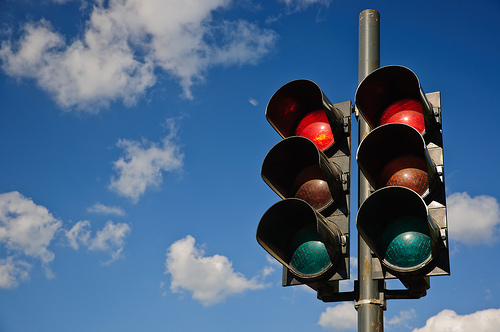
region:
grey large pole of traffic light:
[345, 3, 400, 325]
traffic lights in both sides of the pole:
[252, 66, 445, 296]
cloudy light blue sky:
[0, 8, 499, 325]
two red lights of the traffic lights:
[276, 78, 433, 140]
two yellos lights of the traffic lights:
[263, 136, 448, 200]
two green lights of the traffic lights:
[269, 209, 434, 274]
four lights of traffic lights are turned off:
[265, 130, 450, 285]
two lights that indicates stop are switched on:
[280, 68, 435, 158]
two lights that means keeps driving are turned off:
[271, 196, 447, 278]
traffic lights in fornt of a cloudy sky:
[258, 6, 447, 330]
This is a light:
[248, 16, 475, 310]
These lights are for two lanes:
[260, 70, 464, 308]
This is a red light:
[263, 55, 448, 142]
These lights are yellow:
[263, 125, 445, 199]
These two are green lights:
[237, 182, 465, 286]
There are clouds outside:
[18, 13, 465, 330]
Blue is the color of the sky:
[10, 8, 485, 313]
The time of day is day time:
[30, 11, 476, 311]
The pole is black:
[296, 1, 442, 321]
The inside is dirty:
[251, 69, 358, 159]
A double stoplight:
[258, 15, 456, 315]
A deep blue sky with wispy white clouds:
[13, 11, 244, 326]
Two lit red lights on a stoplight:
[263, 75, 443, 136]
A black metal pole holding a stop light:
[347, 8, 389, 328]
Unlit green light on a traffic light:
[257, 200, 346, 285]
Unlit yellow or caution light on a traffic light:
[354, 123, 444, 194]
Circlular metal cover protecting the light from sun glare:
[250, 195, 341, 275]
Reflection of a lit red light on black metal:
[276, 92, 299, 118]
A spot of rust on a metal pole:
[357, 255, 373, 281]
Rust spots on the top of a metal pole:
[355, 8, 385, 27]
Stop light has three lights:
[257, 8, 450, 330]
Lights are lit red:
[276, 105, 432, 148]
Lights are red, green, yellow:
[255, 65, 446, 297]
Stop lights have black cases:
[250, 60, 446, 293]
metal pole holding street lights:
[355, 5, 390, 328]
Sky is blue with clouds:
[0, 0, 498, 327]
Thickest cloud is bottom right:
[407, 305, 497, 325]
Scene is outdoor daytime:
[1, 1, 496, 328]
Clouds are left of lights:
[0, 0, 261, 306]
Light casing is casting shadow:
[256, 7, 450, 330]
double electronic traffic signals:
[258, 9, 451, 325]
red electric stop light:
[269, 90, 334, 148]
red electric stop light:
[364, 76, 428, 133]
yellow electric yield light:
[275, 153, 334, 210]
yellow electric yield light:
[361, 150, 432, 197]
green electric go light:
[273, 223, 338, 278]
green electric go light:
[372, 214, 437, 269]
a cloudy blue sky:
[8, 4, 498, 322]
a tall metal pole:
[353, 4, 386, 330]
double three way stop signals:
[250, 65, 452, 307]